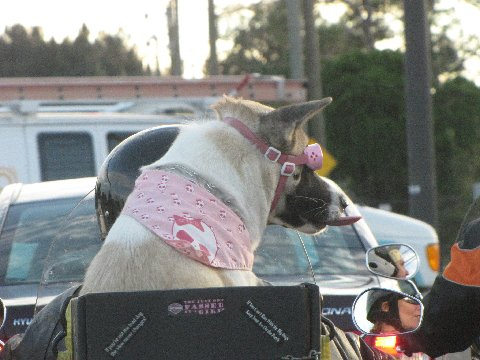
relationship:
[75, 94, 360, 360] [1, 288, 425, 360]
dog riding motorcycle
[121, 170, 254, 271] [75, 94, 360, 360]
scarf on dog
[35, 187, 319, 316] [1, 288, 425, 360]
windshield on motorcycle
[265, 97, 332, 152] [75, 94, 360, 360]
ear of dog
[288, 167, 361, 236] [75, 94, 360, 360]
mouth on dog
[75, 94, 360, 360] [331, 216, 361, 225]
dog sticking out tongue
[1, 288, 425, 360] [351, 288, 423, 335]
motorcycle side mirror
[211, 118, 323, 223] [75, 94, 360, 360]
goggles on dog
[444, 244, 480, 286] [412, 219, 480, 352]
stripe on jacket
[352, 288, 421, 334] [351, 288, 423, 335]
reflection in mirror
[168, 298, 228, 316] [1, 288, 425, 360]
sticker on motorcycle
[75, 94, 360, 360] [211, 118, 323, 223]
dog wearing goggles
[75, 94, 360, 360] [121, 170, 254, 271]
dog wearing scarf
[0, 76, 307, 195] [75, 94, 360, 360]
van behind dog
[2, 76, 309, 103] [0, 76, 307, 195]
ladder on van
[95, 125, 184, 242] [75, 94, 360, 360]
helmet behind dog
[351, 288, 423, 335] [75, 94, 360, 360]
mirror next to dog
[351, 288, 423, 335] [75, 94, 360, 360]
mirror above dog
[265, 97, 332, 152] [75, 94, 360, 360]
ear on dog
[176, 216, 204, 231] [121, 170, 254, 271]
bow on scarf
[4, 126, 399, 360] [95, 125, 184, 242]
person wearing helmet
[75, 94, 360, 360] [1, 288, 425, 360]
dog on motorcycle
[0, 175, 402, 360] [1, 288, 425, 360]
car in front of motorcycle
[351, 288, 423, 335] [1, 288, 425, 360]
mirror on motorcycle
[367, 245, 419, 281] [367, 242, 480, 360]
mirror on motorcycle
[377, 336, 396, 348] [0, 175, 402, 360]
light on car